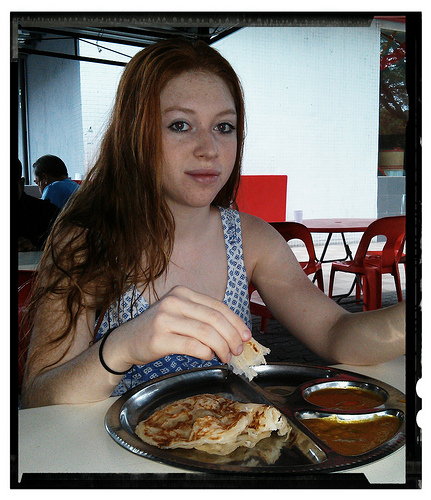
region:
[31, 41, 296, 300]
woman with long red hair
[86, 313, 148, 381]
black hair band on wrist of woman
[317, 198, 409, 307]
red plastic lawn chair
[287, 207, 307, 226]
white plastic cup on table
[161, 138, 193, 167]
red freckles on cheek of woman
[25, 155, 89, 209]
man in blue shirt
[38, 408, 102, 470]
white top of table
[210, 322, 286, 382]
piece of food in hand of woman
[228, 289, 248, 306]
design on blouse of woman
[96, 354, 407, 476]
metal serving plate on table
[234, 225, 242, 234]
small blue design on shirt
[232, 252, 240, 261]
small blue design on shirt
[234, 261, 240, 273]
small blue design on shirt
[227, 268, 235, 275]
small blue design on shirt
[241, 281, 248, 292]
small blue design on shirt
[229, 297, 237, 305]
small blue design on shirt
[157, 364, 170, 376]
small blue design on shirt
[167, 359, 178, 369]
small blue design on shirt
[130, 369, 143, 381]
small blue design on shirt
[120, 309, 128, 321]
small blue design on shirt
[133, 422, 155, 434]
part of a plate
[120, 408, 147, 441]
edge of a plate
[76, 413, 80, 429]
part of a table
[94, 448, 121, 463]
edge of a table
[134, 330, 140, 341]
part of a shirt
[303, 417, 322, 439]
part of a soup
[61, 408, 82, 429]
side of a table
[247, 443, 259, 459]
part of a plate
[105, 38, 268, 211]
head of a person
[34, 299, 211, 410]
arm of a person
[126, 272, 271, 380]
hand of a person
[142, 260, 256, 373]
finger of a person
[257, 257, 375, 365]
arm of a person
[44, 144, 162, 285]
hair of a person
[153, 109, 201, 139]
eye of a person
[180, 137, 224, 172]
nose of a person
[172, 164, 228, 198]
mouth of a person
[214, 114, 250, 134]
an eye of a person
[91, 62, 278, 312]
girl has red hair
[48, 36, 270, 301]
girl has long hair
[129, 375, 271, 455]
white and brown bread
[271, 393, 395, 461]
two sauces on plate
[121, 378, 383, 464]
bread on silver plate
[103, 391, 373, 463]
plate on white table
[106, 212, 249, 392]
blue and white dress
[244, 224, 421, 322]
red chairs at table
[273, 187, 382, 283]
red and metal table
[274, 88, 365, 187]
white wall behind girl